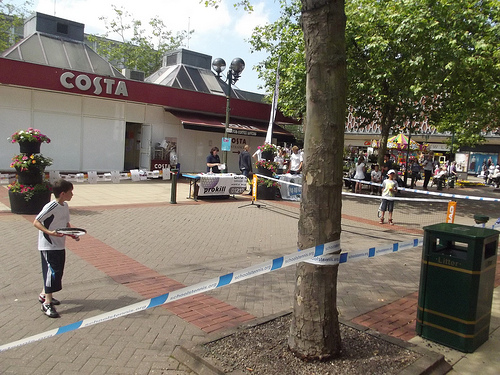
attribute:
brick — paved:
[144, 271, 157, 280]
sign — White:
[58, 72, 128, 97]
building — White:
[0, 12, 302, 182]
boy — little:
[26, 179, 93, 322]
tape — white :
[3, 234, 425, 366]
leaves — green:
[250, 1, 497, 156]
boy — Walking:
[34, 179, 81, 317]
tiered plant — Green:
[7, 129, 52, 211]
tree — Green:
[244, 0, 490, 195]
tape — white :
[56, 263, 318, 319]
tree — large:
[266, 2, 493, 173]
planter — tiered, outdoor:
[7, 129, 52, 211]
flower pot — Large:
[3, 127, 51, 215]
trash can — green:
[415, 220, 499, 354]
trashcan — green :
[408, 211, 497, 360]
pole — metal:
[221, 53, 262, 178]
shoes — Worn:
[33, 294, 63, 319]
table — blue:
[184, 172, 251, 201]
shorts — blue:
[23, 247, 103, 293]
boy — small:
[359, 142, 438, 217]